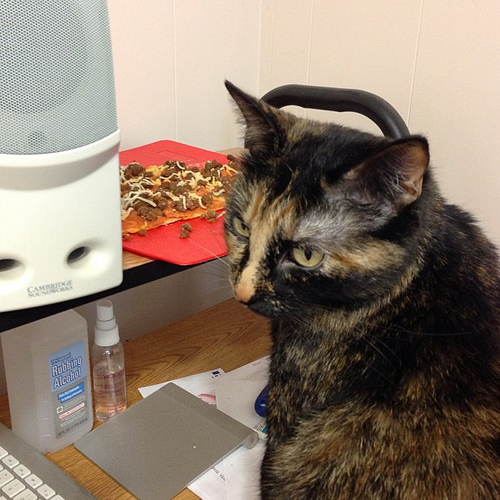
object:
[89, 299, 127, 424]
bottle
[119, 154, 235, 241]
food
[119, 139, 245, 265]
plate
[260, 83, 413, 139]
bar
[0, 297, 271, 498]
desk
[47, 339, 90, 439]
label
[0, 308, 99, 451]
bottle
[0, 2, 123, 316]
computer speaker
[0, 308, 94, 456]
alcohol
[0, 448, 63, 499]
computer keyboard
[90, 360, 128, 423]
alcohol